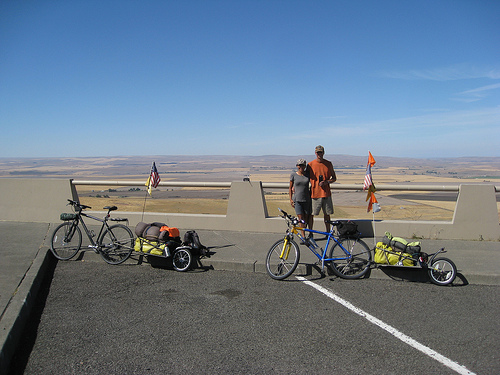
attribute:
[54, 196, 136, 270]
bicycle — black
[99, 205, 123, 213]
seat — black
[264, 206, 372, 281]
bicycle — blue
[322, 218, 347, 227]
seat — black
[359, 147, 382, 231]
flags — colored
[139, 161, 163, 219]
flag — american, usa, hanging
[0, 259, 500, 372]
parking lot — gray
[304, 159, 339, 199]
shirt — orange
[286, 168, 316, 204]
shirt — gray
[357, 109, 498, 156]
clouds — white, whit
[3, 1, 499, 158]
sky — blue, blue', clear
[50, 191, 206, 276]
bike — black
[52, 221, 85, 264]
tire — black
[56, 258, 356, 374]
pavement — black, cement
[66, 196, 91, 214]
handle bars — black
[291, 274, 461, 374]
line — painted, white